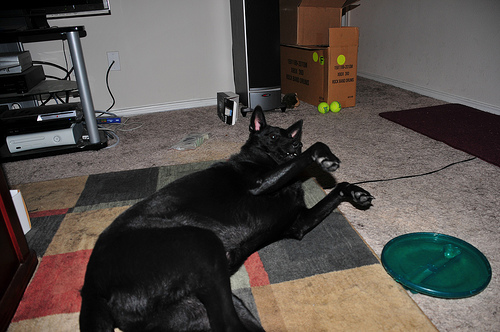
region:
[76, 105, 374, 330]
a dog lying on the floor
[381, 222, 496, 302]
a green dog frisbee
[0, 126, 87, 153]
a white Xbox game console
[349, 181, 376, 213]
the paw of a dog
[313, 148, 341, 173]
the paw of a dog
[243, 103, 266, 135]
the ear of a dog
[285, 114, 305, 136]
the ear of a dog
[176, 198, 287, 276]
the belly of a dog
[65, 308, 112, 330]
the tail of a dog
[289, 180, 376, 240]
the leg of a dog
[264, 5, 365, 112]
two cardboard boxes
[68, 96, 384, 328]
a dog color black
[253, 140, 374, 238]
front legs of dog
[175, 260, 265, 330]
back legs of dog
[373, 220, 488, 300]
a green dish on floor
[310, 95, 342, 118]
two balls on a floor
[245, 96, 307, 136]
two pointy ears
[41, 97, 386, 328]
dog lying on a mat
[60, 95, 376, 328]
the dog is color black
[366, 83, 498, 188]
a black rug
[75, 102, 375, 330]
Black big dog laying down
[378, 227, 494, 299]
Green plastic plate on the floor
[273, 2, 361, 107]
Cardboard boxes standing on the floor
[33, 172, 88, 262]
Colorful rug on the floor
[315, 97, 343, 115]
Two tennis green balls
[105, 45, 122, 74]
Wall wire outlet connection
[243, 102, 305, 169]
Black dog's awake face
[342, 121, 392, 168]
Light grey carpet laying down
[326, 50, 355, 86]
Printed text on a cardboard box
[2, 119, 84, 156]
Remote control electric appliance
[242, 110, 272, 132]
Dog has black ear.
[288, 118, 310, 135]
Dog has black ear.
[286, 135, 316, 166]
Dog has black nose.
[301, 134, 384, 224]
Dog has black paws.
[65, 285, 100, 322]
Dog has black tail.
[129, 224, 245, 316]
Dog has black back leg.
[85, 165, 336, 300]
Dog laying on colorful rug.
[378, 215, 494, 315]
Green frisbee on ground.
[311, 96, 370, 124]
2 tennis balls near box.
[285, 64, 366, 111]
Cardboard box on floor.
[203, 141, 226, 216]
There is a black dog visible here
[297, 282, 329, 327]
There is a rug that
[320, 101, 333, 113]
There are yellow tennis balls here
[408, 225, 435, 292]
There is a frisbee that is here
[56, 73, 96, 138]
There is a television stand visible here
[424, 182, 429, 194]
There is beige carpeting that is visible here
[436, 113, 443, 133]
There is a maroon rug that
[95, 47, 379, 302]
This room looks quite untidy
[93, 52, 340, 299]
This room is in a gigantic house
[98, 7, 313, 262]
This room is stationed in Kennebunkeport, Maine